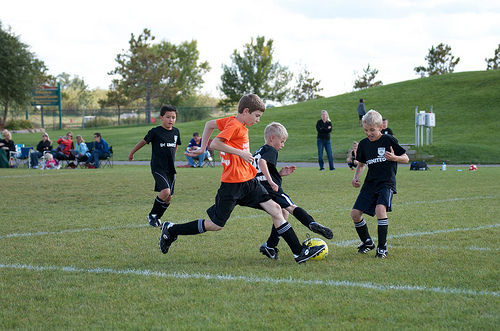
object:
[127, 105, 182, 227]
boy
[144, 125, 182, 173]
shirt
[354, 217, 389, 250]
socks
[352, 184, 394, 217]
shorts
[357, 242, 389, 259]
black shoes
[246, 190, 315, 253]
leg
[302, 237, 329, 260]
ball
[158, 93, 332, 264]
boy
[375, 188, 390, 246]
leg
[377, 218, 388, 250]
shin guard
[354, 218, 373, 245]
shin guard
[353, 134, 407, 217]
uniform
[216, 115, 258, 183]
orange shirt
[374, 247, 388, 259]
soccer shoe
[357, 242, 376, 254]
soccer shoe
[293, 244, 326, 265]
soccer shoe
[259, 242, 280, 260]
soccer shoe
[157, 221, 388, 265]
shoes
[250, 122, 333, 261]
boy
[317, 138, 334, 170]
jeans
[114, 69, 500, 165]
wall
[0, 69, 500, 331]
grass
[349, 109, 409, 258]
boy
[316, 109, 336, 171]
person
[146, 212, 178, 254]
shoes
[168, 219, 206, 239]
sock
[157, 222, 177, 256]
shoe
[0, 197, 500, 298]
line